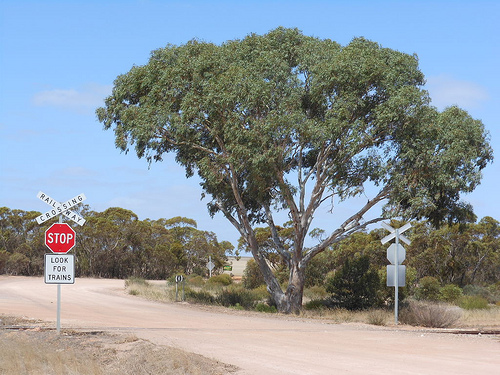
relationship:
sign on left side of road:
[34, 190, 87, 336] [2, 266, 484, 373]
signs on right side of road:
[375, 212, 424, 336] [50, 256, 477, 373]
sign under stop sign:
[34, 190, 87, 336] [42, 222, 82, 254]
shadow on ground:
[431, 321, 498, 337] [5, 270, 496, 371]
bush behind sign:
[335, 243, 389, 312] [375, 209, 405, 321]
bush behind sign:
[415, 209, 498, 288] [375, 209, 405, 321]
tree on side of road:
[92, 25, 499, 312] [2, 266, 484, 373]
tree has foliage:
[92, 25, 499, 312] [96, 24, 493, 239]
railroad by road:
[0, 326, 500, 335] [2, 266, 484, 373]